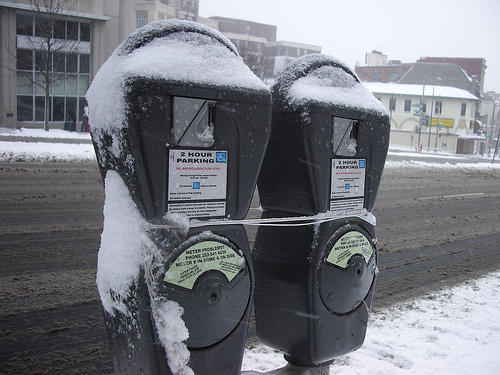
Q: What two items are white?
A: Stickers.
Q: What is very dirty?
A: The road.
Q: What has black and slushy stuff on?
A: The road.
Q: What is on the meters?
A: White snow.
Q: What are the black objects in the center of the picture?
A: Parking meters.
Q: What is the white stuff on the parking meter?
A: Snow.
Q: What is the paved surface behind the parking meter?
A: A street.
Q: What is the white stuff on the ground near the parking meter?
A: Snow.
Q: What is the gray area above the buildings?
A: The sky.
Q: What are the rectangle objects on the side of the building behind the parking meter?
A: Windows.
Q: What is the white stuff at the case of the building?
A: Snow.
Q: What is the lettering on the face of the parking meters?
A: Words.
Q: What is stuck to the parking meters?
A: Ice and snow.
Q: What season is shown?
A: Winter.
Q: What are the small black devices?
A: Parking meters.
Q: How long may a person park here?
A: 2 hours.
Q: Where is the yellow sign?
A: On a house.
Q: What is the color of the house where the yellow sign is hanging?
A: White.